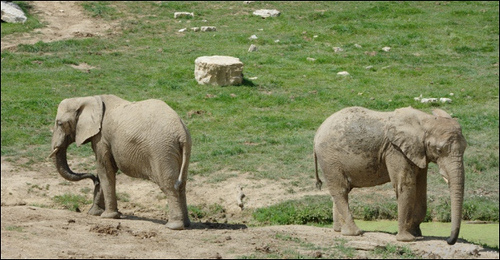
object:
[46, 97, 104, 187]
head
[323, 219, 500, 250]
stream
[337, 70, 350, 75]
rock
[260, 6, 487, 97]
lawn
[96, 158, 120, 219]
legs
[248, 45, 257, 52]
rocks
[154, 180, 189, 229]
legs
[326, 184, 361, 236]
legs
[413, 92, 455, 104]
rock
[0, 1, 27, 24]
rock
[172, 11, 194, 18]
rock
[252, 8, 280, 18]
rock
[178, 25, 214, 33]
rock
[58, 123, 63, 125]
eye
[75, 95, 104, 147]
ear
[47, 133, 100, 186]
trunk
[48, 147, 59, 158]
tusks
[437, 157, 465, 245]
trunk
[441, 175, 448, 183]
tusk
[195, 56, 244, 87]
boulder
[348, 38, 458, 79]
grass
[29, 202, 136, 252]
dirt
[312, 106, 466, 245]
elephant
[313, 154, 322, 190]
tail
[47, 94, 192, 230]
elephant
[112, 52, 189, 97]
grass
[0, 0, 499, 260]
field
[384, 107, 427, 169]
ears